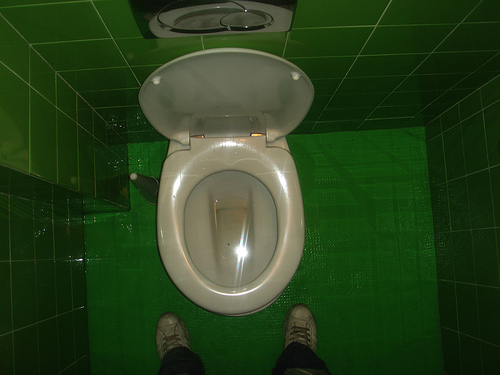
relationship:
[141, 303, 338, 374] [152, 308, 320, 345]
person wearing shoes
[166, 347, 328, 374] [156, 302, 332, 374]
blue jeans on person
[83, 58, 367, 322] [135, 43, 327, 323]
seat of toilet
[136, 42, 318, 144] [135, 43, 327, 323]
lid of toilet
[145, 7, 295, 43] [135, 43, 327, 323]
mirror above toilet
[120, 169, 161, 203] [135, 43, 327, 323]
brush beside toilet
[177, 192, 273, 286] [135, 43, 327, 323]
water inside toilet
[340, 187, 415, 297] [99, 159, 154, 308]
item on floor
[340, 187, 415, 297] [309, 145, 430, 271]
item on floor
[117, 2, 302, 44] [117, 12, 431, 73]
paper dispenser on wall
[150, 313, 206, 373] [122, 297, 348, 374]
leg of a man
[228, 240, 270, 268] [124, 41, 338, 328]
glare in toilet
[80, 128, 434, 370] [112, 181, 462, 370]
tile on floor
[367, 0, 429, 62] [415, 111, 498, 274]
tile on wall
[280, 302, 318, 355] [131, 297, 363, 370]
shoe on feet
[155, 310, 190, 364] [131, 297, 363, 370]
shoe on feet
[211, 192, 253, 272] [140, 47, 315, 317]
water in toilet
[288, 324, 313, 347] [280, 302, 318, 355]
shoelaces on shoe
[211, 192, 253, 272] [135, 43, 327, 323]
water in toilet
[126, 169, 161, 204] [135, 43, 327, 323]
brush next to toilet